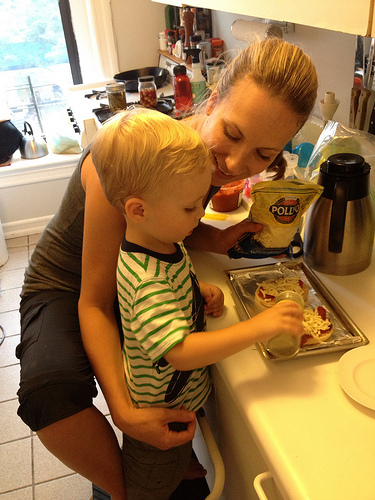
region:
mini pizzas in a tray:
[220, 253, 366, 367]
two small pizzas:
[234, 260, 362, 353]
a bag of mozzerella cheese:
[240, 179, 325, 258]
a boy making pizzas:
[62, 97, 341, 492]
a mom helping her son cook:
[8, 31, 334, 471]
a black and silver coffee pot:
[307, 145, 371, 283]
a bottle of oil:
[264, 280, 307, 361]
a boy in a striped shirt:
[80, 98, 321, 488]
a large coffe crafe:
[303, 151, 373, 275]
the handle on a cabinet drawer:
[244, 461, 279, 499]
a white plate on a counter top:
[321, 341, 373, 419]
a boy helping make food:
[256, 279, 325, 366]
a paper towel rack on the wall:
[217, 15, 293, 55]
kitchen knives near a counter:
[344, 37, 373, 133]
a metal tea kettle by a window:
[12, 117, 52, 162]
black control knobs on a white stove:
[61, 100, 84, 139]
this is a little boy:
[99, 95, 231, 497]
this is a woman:
[2, 15, 349, 499]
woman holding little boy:
[4, 35, 339, 491]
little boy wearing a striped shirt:
[97, 244, 239, 437]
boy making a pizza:
[57, 130, 344, 398]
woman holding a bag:
[223, 149, 323, 279]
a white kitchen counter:
[225, 328, 365, 493]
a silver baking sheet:
[211, 230, 362, 391]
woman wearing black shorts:
[4, 265, 128, 440]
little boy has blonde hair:
[73, 113, 234, 221]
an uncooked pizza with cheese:
[251, 276, 312, 306]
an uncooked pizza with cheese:
[278, 300, 336, 349]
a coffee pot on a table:
[299, 148, 374, 277]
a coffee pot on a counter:
[14, 120, 50, 158]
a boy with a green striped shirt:
[116, 231, 214, 418]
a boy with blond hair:
[91, 102, 214, 211]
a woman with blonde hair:
[180, 37, 320, 124]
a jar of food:
[103, 79, 129, 113]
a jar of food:
[134, 73, 159, 111]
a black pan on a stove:
[109, 66, 171, 92]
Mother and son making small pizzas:
[15, 35, 324, 499]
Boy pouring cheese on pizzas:
[89, 105, 304, 499]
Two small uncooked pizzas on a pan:
[225, 257, 370, 362]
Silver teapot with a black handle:
[17, 121, 48, 160]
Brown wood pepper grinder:
[178, 5, 197, 63]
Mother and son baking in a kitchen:
[13, 37, 317, 498]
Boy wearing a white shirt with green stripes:
[87, 103, 303, 499]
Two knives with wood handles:
[346, 32, 373, 135]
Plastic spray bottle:
[181, 46, 206, 108]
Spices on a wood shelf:
[154, 4, 224, 75]